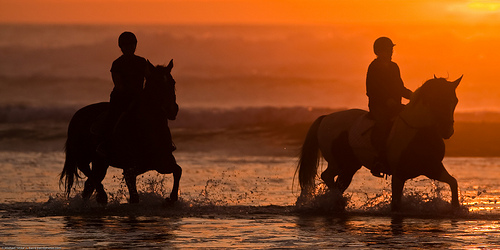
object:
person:
[110, 33, 148, 144]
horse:
[58, 59, 183, 208]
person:
[366, 37, 412, 168]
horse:
[298, 73, 461, 222]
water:
[3, 159, 500, 250]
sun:
[443, 0, 500, 23]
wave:
[0, 178, 497, 217]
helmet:
[117, 32, 138, 47]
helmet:
[373, 36, 395, 52]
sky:
[0, 0, 500, 23]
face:
[150, 66, 181, 121]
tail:
[61, 122, 78, 195]